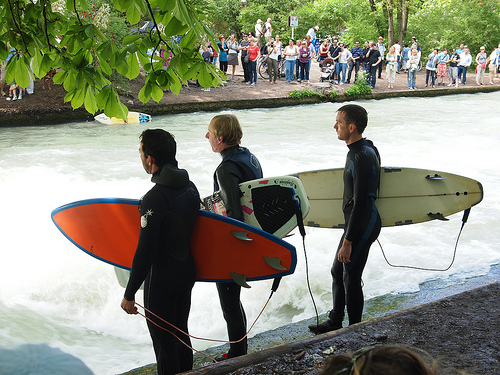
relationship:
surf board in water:
[96, 112, 154, 129] [3, 90, 499, 375]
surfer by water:
[308, 98, 388, 334] [3, 90, 499, 375]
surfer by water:
[195, 111, 275, 362] [3, 90, 499, 375]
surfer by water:
[128, 127, 207, 369] [3, 90, 499, 375]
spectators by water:
[195, 32, 487, 85] [3, 90, 499, 375]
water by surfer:
[3, 90, 499, 375] [308, 98, 388, 334]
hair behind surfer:
[318, 345, 424, 374] [308, 98, 388, 334]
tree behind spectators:
[362, 2, 418, 76] [195, 32, 487, 85]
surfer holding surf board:
[128, 127, 207, 369] [53, 197, 299, 294]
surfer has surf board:
[308, 98, 388, 334] [286, 160, 490, 234]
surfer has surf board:
[128, 127, 207, 369] [53, 197, 299, 294]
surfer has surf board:
[195, 111, 275, 362] [197, 179, 307, 251]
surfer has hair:
[128, 127, 207, 369] [141, 123, 183, 171]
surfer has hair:
[195, 111, 275, 362] [209, 109, 241, 151]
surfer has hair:
[308, 98, 388, 334] [336, 104, 369, 137]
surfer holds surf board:
[128, 127, 207, 369] [53, 197, 299, 294]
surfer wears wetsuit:
[308, 98, 388, 334] [329, 141, 383, 325]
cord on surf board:
[377, 207, 479, 279] [286, 160, 490, 234]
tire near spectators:
[261, 59, 272, 86] [195, 32, 487, 85]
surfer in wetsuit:
[308, 98, 388, 334] [329, 141, 383, 325]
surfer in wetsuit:
[195, 111, 275, 362] [212, 146, 260, 336]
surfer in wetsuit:
[128, 127, 207, 369] [118, 163, 211, 372]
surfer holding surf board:
[308, 98, 388, 334] [286, 160, 490, 234]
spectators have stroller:
[195, 32, 487, 85] [314, 59, 337, 90]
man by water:
[362, 43, 386, 87] [3, 90, 499, 375]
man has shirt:
[362, 43, 386, 87] [364, 48, 379, 64]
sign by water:
[286, 16, 299, 26] [3, 90, 499, 375]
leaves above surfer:
[55, 30, 131, 124] [128, 127, 207, 369]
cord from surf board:
[377, 207, 479, 279] [286, 160, 490, 234]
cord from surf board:
[290, 209, 327, 336] [197, 179, 307, 251]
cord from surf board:
[127, 273, 294, 364] [53, 197, 299, 294]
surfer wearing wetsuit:
[308, 98, 388, 334] [329, 141, 383, 325]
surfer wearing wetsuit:
[195, 111, 275, 362] [212, 146, 260, 336]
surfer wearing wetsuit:
[128, 127, 207, 369] [118, 163, 211, 372]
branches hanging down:
[5, 4, 230, 112] [132, 364, 135, 368]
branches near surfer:
[5, 4, 230, 112] [128, 127, 207, 369]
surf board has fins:
[53, 197, 299, 294] [228, 244, 282, 291]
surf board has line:
[286, 160, 490, 234] [309, 193, 454, 204]